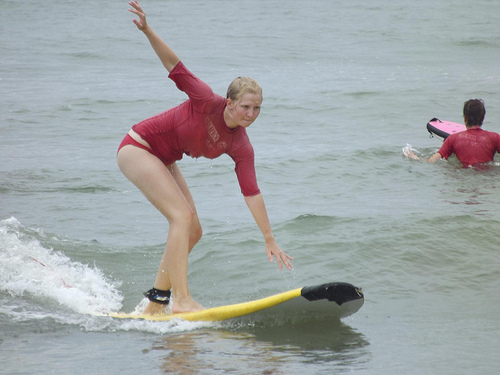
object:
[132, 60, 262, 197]
bathing suit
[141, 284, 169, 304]
ankle tie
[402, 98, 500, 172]
surfer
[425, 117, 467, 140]
pink surfboard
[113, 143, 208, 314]
leg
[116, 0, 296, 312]
girl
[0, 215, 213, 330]
foam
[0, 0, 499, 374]
ocean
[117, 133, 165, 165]
bikini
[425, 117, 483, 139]
surfboard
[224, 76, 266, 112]
blonde hair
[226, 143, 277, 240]
arm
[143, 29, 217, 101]
arm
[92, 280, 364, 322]
surfboard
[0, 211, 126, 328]
waves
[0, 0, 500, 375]
water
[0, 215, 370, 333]
surfing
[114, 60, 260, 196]
red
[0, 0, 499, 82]
air